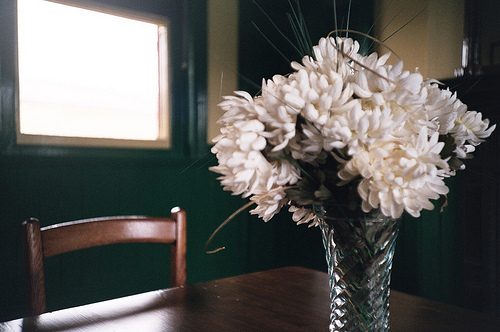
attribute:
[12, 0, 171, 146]
frame — white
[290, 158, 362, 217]
stems — green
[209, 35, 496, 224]
flowers — white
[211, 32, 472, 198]
flowers — white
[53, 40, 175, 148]
light — bright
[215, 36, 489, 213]
flowers — white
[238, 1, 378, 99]
corner room — dark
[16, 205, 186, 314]
chair — brown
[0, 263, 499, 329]
table — brown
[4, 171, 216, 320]
wall — green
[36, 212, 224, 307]
chair — wooden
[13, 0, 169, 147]
window — light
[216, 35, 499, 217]
bouquet — large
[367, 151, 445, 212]
flower — white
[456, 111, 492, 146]
flower — white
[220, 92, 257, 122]
flower — white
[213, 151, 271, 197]
flower — white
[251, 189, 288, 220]
flower — white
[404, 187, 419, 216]
petals — white, curved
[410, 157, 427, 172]
petals — white, curved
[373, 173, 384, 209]
petals — white, curved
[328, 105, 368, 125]
petals — white, curved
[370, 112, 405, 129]
petals — white, curved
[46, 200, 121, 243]
chair — Top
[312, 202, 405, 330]
vase — clear, glass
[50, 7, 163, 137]
daylight —  shines